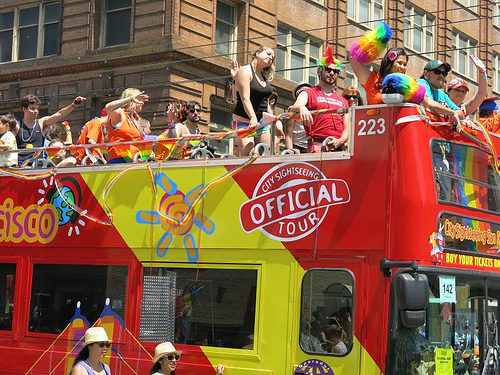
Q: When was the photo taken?
A: Daytime.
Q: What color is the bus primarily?
A: Red.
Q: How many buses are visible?
A: One.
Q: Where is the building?
A: Background.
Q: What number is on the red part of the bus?
A: 223.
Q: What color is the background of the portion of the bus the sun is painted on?
A: Yellow.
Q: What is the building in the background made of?
A: Bricks.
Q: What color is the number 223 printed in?
A: White.